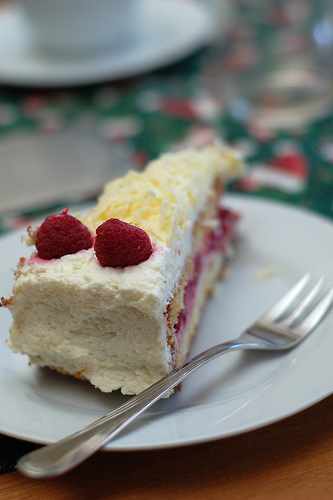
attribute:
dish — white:
[1, 188, 333, 451]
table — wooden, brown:
[1, 2, 331, 499]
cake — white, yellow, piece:
[5, 146, 236, 395]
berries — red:
[38, 216, 153, 268]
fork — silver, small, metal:
[13, 272, 331, 480]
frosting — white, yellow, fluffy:
[9, 250, 184, 405]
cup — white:
[18, 3, 134, 54]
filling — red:
[166, 223, 234, 344]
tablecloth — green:
[3, 4, 332, 472]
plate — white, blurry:
[17, 364, 332, 489]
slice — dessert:
[19, 146, 231, 392]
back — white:
[10, 263, 166, 405]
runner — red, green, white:
[2, 0, 332, 473]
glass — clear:
[207, 1, 332, 124]